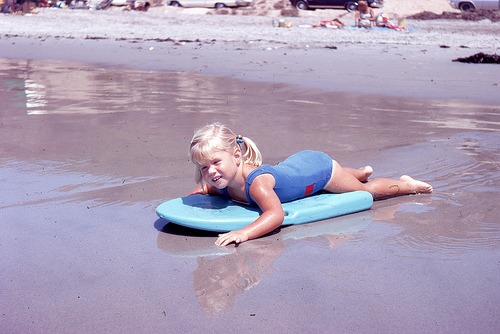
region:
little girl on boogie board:
[118, 108, 446, 257]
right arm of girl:
[200, 216, 280, 268]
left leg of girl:
[366, 173, 450, 211]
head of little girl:
[180, 110, 265, 192]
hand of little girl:
[213, 225, 244, 252]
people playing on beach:
[329, 0, 406, 39]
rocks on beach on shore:
[161, 26, 222, 58]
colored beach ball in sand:
[373, 9, 386, 29]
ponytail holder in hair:
[231, 134, 243, 146]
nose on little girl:
[206, 167, 218, 179]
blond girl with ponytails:
[175, 94, 275, 246]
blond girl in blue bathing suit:
[191, 120, 389, 215]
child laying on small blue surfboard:
[150, 125, 380, 240]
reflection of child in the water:
[103, 215, 415, 318]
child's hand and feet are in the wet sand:
[147, 137, 445, 247]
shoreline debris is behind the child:
[25, 23, 467, 128]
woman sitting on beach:
[301, 0, 378, 43]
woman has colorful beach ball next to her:
[373, 11, 410, 45]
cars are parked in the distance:
[74, 0, 485, 27]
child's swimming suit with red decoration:
[295, 172, 324, 206]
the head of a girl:
[181, 120, 266, 195]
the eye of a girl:
[210, 156, 223, 166]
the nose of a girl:
[201, 161, 218, 174]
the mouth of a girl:
[206, 170, 223, 185]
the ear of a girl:
[230, 145, 245, 165]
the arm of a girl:
[237, 171, 287, 237]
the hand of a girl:
[210, 225, 252, 250]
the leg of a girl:
[323, 155, 410, 200]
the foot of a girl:
[400, 170, 435, 192]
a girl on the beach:
[170, 117, 437, 249]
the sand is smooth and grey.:
[36, 65, 148, 245]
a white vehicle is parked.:
[156, 0, 241, 10]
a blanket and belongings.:
[265, 10, 350, 30]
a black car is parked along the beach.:
[290, 0, 370, 10]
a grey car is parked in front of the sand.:
[450, 0, 495, 20]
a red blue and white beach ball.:
[373, 7, 390, 31]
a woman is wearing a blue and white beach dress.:
[351, 4, 381, 31]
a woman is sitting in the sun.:
[294, 0, 416, 32]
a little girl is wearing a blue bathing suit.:
[272, 152, 335, 193]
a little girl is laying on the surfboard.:
[140, 118, 424, 241]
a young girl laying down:
[179, 123, 431, 255]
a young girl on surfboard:
[143, 124, 436, 252]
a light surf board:
[153, 188, 374, 233]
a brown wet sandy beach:
[9, 64, 491, 331]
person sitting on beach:
[354, 1, 374, 27]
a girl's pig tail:
[236, 130, 262, 164]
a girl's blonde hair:
[182, 122, 262, 172]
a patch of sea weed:
[449, 48, 499, 67]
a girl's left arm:
[210, 172, 282, 253]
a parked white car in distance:
[164, 0, 244, 8]